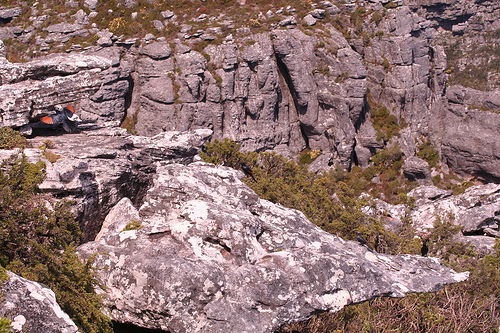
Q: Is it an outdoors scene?
A: Yes, it is outdoors.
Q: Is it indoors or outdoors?
A: It is outdoors.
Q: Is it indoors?
A: No, it is outdoors.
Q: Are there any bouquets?
A: No, there are no bouquets.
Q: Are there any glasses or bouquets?
A: No, there are no bouquets or glasses.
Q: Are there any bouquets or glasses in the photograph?
A: No, there are no bouquets or glasses.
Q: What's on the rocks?
A: The bush is on the rocks.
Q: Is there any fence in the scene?
A: No, there are no fences.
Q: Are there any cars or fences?
A: No, there are no fences or cars.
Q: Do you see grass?
A: Yes, there is grass.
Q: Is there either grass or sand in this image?
A: Yes, there is grass.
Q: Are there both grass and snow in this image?
A: No, there is grass but no snow.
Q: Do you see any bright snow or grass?
A: Yes, there is bright grass.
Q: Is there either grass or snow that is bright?
A: Yes, the grass is bright.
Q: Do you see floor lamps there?
A: No, there are no floor lamps.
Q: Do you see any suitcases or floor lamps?
A: No, there are no floor lamps or suitcases.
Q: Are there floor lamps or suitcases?
A: No, there are no floor lamps or suitcases.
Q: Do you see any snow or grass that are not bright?
A: No, there is grass but it is bright.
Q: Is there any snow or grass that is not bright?
A: No, there is grass but it is bright.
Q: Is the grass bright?
A: Yes, the grass is bright.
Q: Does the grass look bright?
A: Yes, the grass is bright.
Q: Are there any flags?
A: No, there are no flags.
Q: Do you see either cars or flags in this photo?
A: No, there are no flags or cars.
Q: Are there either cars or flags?
A: No, there are no flags or cars.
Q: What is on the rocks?
A: The shrub is on the rocks.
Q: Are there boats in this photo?
A: No, there are no boats.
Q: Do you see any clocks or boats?
A: No, there are no boats or clocks.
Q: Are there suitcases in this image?
A: No, there are no suitcases.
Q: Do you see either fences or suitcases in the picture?
A: No, there are no suitcases or fences.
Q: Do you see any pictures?
A: No, there are no pictures.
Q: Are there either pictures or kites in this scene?
A: No, there are no pictures or kites.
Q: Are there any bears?
A: Yes, there is a bear.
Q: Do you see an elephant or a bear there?
A: Yes, there is a bear.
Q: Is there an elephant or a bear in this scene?
A: Yes, there is a bear.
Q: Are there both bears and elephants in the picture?
A: No, there is a bear but no elephants.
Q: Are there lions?
A: No, there are no lions.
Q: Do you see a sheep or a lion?
A: No, there are no lions or sheep.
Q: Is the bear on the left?
A: Yes, the bear is on the left of the image.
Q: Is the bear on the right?
A: No, the bear is on the left of the image.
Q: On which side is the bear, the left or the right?
A: The bear is on the left of the image.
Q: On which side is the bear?
A: The bear is on the left of the image.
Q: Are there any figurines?
A: No, there are no figurines.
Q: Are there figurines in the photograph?
A: No, there are no figurines.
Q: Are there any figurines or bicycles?
A: No, there are no figurines or bicycles.